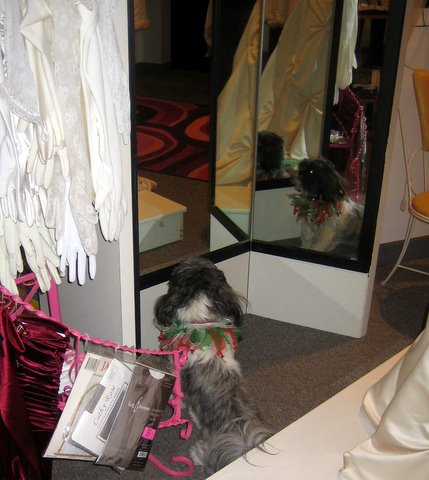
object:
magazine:
[96, 363, 178, 475]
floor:
[50, 254, 429, 480]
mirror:
[251, 2, 392, 260]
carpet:
[50, 255, 429, 480]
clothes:
[43, 0, 100, 256]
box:
[138, 189, 188, 255]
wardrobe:
[0, 0, 136, 354]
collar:
[158, 317, 239, 353]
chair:
[377, 63, 428, 287]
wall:
[377, 1, 429, 246]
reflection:
[288, 153, 364, 252]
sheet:
[336, 321, 429, 480]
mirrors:
[133, 0, 264, 277]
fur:
[205, 364, 233, 403]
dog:
[152, 258, 279, 476]